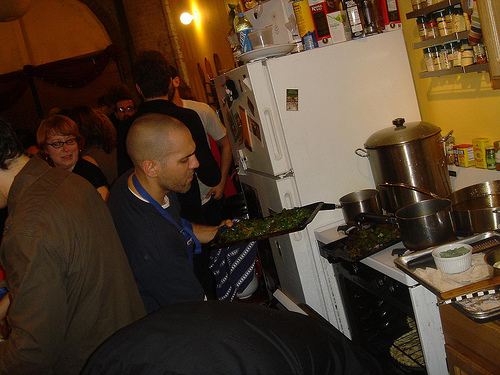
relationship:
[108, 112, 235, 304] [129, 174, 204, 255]
man wearing lanyard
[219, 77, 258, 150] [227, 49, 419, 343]
magnets on fridge